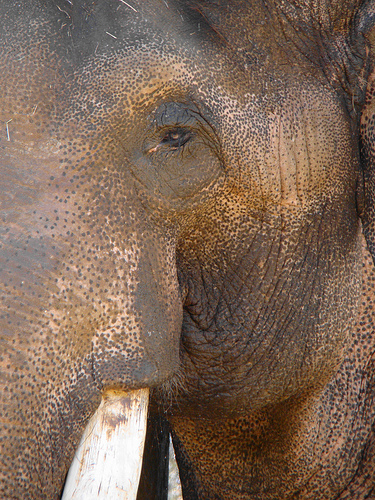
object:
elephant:
[1, 1, 375, 500]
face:
[3, 4, 345, 427]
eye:
[147, 122, 199, 150]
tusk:
[58, 385, 161, 500]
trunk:
[0, 382, 104, 499]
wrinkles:
[167, 156, 356, 424]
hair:
[150, 349, 191, 446]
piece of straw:
[104, 31, 119, 41]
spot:
[49, 175, 56, 181]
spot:
[100, 402, 129, 436]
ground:
[166, 435, 185, 499]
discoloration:
[2, 219, 154, 393]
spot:
[114, 250, 122, 257]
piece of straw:
[120, 1, 137, 13]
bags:
[129, 146, 227, 204]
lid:
[147, 99, 210, 139]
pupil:
[171, 132, 179, 137]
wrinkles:
[128, 78, 228, 204]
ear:
[321, 3, 375, 261]